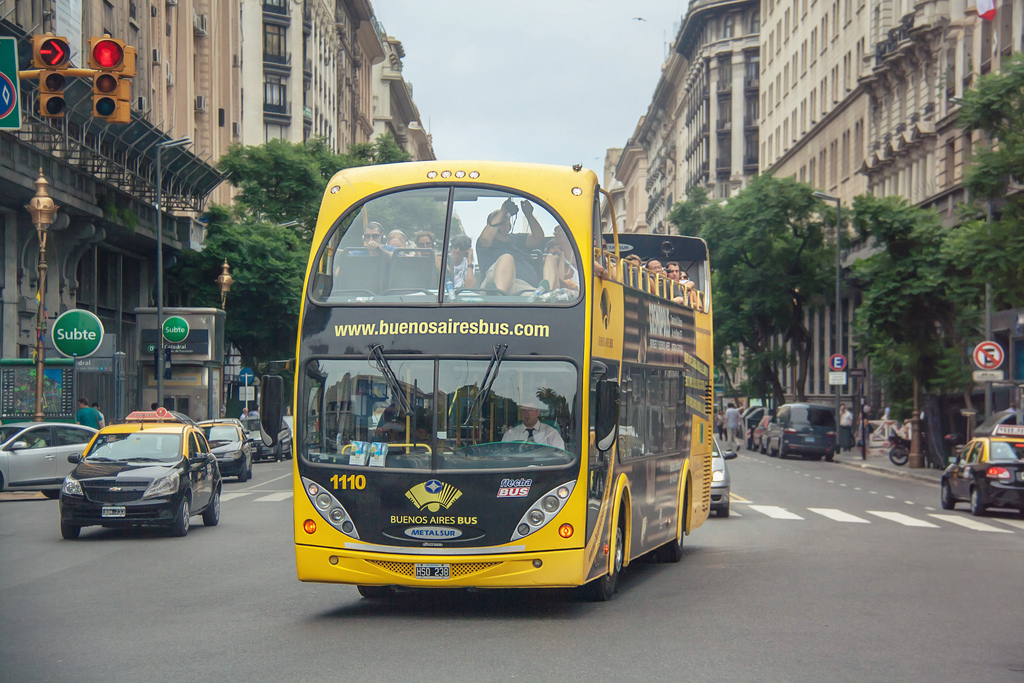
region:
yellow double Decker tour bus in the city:
[296, 158, 720, 595]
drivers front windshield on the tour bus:
[297, 348, 588, 473]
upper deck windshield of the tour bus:
[310, 160, 595, 317]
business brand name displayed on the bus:
[313, 306, 567, 352]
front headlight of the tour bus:
[511, 474, 581, 547]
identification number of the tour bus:
[328, 467, 370, 496]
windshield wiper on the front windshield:
[366, 329, 436, 443]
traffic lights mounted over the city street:
[0, 25, 138, 131]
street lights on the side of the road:
[147, 129, 208, 409]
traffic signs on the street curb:
[967, 339, 1007, 428]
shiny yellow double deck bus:
[236, 99, 749, 628]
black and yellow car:
[62, 410, 231, 546]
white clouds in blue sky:
[425, 21, 479, 60]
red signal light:
[88, 34, 140, 134]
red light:
[19, 6, 78, 130]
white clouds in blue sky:
[587, 17, 614, 47]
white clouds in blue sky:
[483, 59, 521, 113]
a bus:
[284, 165, 613, 574]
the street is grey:
[762, 550, 855, 645]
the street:
[829, 577, 944, 660]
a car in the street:
[61, 413, 220, 540]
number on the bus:
[322, 468, 368, 501]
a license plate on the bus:
[407, 558, 461, 585]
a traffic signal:
[85, 36, 137, 100]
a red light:
[88, 32, 128, 75]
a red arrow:
[35, 39, 62, 69]